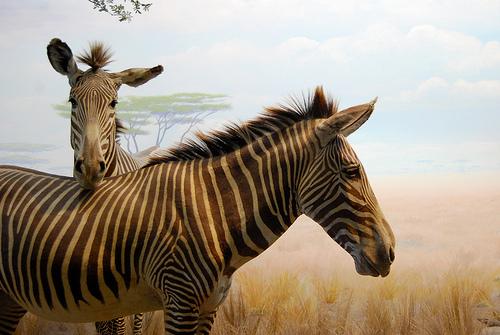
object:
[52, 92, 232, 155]
tree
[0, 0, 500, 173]
cloud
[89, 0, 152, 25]
leaves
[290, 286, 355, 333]
grass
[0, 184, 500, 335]
field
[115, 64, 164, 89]
ear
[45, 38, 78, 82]
ear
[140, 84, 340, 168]
hair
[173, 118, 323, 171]
spine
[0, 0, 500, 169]
cloudy sky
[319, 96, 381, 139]
ears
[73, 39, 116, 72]
hair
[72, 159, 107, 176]
nose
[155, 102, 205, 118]
leaves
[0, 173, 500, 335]
pasture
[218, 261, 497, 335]
wheat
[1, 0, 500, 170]
sky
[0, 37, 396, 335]
animals